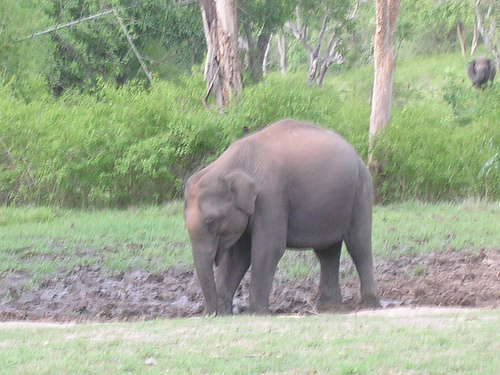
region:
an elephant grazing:
[173, 88, 385, 331]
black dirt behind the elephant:
[95, 277, 137, 313]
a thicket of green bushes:
[47, 99, 185, 186]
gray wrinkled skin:
[294, 202, 332, 225]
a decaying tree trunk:
[197, 22, 235, 99]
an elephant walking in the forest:
[461, 50, 496, 96]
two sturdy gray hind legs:
[311, 244, 391, 333]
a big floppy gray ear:
[228, 176, 265, 214]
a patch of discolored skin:
[269, 125, 315, 157]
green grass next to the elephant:
[99, 214, 177, 243]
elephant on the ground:
[128, 95, 404, 324]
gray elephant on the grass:
[153, 110, 398, 335]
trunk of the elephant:
[175, 242, 221, 313]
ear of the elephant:
[223, 168, 258, 220]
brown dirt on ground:
[96, 268, 174, 318]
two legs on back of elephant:
[307, 233, 387, 312]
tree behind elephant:
[355, 18, 422, 118]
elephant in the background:
[441, 43, 497, 88]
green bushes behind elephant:
[17, 67, 151, 178]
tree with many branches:
[280, 11, 365, 78]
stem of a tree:
[364, 55, 396, 100]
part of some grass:
[271, 309, 311, 356]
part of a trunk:
[184, 249, 224, 297]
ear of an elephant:
[229, 174, 258, 209]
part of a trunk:
[176, 226, 217, 318]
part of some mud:
[108, 278, 143, 321]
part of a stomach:
[314, 172, 361, 212]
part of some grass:
[138, 205, 158, 227]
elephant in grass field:
[114, 77, 411, 330]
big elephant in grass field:
[80, 56, 436, 344]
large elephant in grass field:
[11, 66, 431, 342]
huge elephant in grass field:
[46, 54, 424, 338]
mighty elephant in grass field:
[68, 78, 427, 338]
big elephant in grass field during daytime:
[82, 81, 406, 347]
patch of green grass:
[82, 331, 464, 369]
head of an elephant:
[156, 164, 256, 266]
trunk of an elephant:
[189, 247, 226, 316]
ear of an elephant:
[228, 168, 263, 226]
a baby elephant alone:
[132, 60, 457, 368]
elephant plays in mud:
[126, 107, 469, 366]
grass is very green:
[431, 335, 468, 365]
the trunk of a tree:
[318, 85, 493, 220]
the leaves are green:
[73, 91, 203, 146]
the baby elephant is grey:
[153, 96, 406, 343]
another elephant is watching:
[435, 35, 498, 112]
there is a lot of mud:
[83, 115, 495, 355]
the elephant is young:
[158, 109, 450, 330]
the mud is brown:
[46, 255, 176, 320]